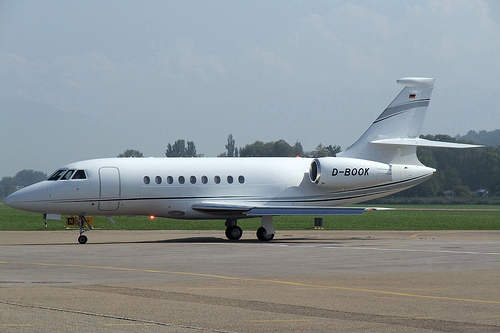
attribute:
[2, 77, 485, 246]
plane — big, white, small, turbo, long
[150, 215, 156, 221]
light — red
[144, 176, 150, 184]
window — small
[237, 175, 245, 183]
window — small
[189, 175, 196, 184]
window — small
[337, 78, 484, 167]
tail — white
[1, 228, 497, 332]
ground — concrete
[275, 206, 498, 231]
grass — green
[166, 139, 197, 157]
tree — green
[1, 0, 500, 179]
sky — hazy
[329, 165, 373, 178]
letters — black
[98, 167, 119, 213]
door — white